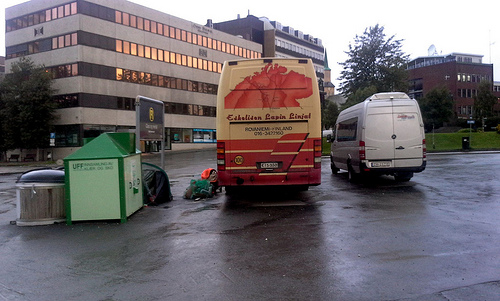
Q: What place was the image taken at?
A: It was taken at the parking lot.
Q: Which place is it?
A: It is a parking lot.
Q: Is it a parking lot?
A: Yes, it is a parking lot.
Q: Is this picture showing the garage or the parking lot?
A: It is showing the parking lot.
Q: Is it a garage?
A: No, it is a parking lot.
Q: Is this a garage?
A: No, it is a parking lot.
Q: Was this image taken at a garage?
A: No, the picture was taken in a parking lot.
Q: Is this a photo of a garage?
A: No, the picture is showing a parking lot.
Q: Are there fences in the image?
A: No, there are no fences.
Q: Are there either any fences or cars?
A: No, there are no fences or cars.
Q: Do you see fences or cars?
A: No, there are no fences or cars.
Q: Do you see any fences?
A: No, there are no fences.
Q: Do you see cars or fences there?
A: No, there are no fences or cars.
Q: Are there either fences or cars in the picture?
A: No, there are no fences or cars.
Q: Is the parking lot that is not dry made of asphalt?
A: Yes, the parking lot is made of asphalt.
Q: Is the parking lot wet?
A: Yes, the parking lot is wet.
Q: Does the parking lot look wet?
A: Yes, the parking lot is wet.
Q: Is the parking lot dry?
A: No, the parking lot is wet.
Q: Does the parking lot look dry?
A: No, the parking lot is wet.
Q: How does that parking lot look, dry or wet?
A: The parking lot is wet.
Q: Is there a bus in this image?
A: Yes, there is a bus.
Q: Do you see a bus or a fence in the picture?
A: Yes, there is a bus.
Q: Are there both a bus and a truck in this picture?
A: No, there is a bus but no trucks.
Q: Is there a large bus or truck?
A: Yes, there is a large bus.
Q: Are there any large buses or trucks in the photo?
A: Yes, there is a large bus.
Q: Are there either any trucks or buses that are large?
A: Yes, the bus is large.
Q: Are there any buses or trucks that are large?
A: Yes, the bus is large.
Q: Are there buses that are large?
A: Yes, there is a large bus.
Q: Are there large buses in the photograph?
A: Yes, there is a large bus.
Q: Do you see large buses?
A: Yes, there is a large bus.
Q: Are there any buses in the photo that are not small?
A: Yes, there is a large bus.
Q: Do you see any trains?
A: No, there are no trains.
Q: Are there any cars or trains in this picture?
A: No, there are no trains or cars.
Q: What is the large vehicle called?
A: The vehicle is a bus.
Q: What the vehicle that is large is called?
A: The vehicle is a bus.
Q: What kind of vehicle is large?
A: The vehicle is a bus.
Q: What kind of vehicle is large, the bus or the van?
A: The bus is large.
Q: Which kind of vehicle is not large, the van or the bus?
A: The van is not large.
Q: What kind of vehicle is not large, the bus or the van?
A: The van is not large.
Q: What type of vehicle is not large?
A: The vehicle is a van.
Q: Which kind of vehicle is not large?
A: The vehicle is a van.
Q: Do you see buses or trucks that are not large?
A: No, there is a bus but it is large.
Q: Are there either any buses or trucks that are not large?
A: No, there is a bus but it is large.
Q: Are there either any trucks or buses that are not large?
A: No, there is a bus but it is large.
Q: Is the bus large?
A: Yes, the bus is large.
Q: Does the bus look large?
A: Yes, the bus is large.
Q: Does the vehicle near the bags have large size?
A: Yes, the bus is large.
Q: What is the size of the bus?
A: The bus is large.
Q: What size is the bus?
A: The bus is large.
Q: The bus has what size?
A: The bus is large.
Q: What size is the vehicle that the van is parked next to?
A: The bus is large.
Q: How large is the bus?
A: The bus is large.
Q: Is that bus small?
A: No, the bus is large.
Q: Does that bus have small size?
A: No, the bus is large.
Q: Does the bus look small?
A: No, the bus is large.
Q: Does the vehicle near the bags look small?
A: No, the bus is large.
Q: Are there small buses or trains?
A: No, there is a bus but it is large.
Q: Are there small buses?
A: No, there is a bus but it is large.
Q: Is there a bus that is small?
A: No, there is a bus but it is large.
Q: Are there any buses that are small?
A: No, there is a bus but it is large.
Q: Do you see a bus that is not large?
A: No, there is a bus but it is large.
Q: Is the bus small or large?
A: The bus is large.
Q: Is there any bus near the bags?
A: Yes, there is a bus near the bags.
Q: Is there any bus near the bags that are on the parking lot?
A: Yes, there is a bus near the bags.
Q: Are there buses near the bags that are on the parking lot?
A: Yes, there is a bus near the bags.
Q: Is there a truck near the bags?
A: No, there is a bus near the bags.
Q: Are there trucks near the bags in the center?
A: No, there is a bus near the bags.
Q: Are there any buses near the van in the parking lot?
A: Yes, there is a bus near the van.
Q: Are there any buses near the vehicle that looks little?
A: Yes, there is a bus near the van.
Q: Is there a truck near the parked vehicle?
A: No, there is a bus near the van.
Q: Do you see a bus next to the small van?
A: Yes, there is a bus next to the van.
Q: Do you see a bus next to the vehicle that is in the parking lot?
A: Yes, there is a bus next to the van.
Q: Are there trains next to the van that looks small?
A: No, there is a bus next to the van.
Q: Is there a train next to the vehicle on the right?
A: No, there is a bus next to the van.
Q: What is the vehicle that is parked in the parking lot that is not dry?
A: The vehicle is a bus.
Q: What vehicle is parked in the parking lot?
A: The vehicle is a bus.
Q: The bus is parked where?
A: The bus is parked in the parking lot.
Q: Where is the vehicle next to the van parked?
A: The bus is parked in the parking lot.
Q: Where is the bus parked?
A: The bus is parked in the parking lot.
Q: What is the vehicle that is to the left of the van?
A: The vehicle is a bus.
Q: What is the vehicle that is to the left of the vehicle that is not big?
A: The vehicle is a bus.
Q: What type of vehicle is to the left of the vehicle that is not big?
A: The vehicle is a bus.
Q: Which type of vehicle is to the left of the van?
A: The vehicle is a bus.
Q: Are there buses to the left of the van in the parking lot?
A: Yes, there is a bus to the left of the van.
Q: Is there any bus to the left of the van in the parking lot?
A: Yes, there is a bus to the left of the van.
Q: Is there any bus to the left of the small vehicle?
A: Yes, there is a bus to the left of the van.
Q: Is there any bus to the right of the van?
A: No, the bus is to the left of the van.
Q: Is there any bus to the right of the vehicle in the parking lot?
A: No, the bus is to the left of the van.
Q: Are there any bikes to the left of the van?
A: No, there is a bus to the left of the van.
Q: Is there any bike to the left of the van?
A: No, there is a bus to the left of the van.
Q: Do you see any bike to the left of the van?
A: No, there is a bus to the left of the van.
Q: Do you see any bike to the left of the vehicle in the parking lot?
A: No, there is a bus to the left of the van.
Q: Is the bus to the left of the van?
A: Yes, the bus is to the left of the van.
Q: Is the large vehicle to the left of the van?
A: Yes, the bus is to the left of the van.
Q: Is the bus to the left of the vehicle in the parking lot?
A: Yes, the bus is to the left of the van.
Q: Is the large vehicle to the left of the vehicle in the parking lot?
A: Yes, the bus is to the left of the van.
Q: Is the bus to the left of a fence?
A: No, the bus is to the left of the van.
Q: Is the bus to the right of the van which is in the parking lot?
A: No, the bus is to the left of the van.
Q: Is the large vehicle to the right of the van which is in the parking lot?
A: No, the bus is to the left of the van.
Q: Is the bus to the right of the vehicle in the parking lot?
A: No, the bus is to the left of the van.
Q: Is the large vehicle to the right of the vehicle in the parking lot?
A: No, the bus is to the left of the van.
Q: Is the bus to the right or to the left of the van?
A: The bus is to the left of the van.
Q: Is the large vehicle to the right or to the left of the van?
A: The bus is to the left of the van.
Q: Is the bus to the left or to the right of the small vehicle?
A: The bus is to the left of the van.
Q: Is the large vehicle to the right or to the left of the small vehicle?
A: The bus is to the left of the van.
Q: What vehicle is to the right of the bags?
A: The vehicle is a bus.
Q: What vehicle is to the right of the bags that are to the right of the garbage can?
A: The vehicle is a bus.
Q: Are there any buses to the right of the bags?
A: Yes, there is a bus to the right of the bags.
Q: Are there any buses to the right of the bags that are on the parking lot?
A: Yes, there is a bus to the right of the bags.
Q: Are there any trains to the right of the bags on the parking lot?
A: No, there is a bus to the right of the bags.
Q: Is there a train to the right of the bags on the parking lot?
A: No, there is a bus to the right of the bags.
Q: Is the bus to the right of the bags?
A: Yes, the bus is to the right of the bags.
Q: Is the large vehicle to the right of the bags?
A: Yes, the bus is to the right of the bags.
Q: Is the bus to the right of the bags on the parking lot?
A: Yes, the bus is to the right of the bags.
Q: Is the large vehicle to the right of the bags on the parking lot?
A: Yes, the bus is to the right of the bags.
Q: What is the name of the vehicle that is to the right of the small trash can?
A: The vehicle is a bus.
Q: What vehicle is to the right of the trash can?
A: The vehicle is a bus.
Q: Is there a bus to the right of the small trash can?
A: Yes, there is a bus to the right of the trashcan.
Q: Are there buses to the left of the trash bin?
A: No, the bus is to the right of the trash bin.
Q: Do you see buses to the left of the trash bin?
A: No, the bus is to the right of the trash bin.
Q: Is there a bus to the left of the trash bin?
A: No, the bus is to the right of the trash bin.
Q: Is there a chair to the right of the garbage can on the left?
A: No, there is a bus to the right of the trashcan.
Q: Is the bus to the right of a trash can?
A: Yes, the bus is to the right of a trash can.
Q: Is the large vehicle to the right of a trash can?
A: Yes, the bus is to the right of a trash can.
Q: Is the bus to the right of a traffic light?
A: No, the bus is to the right of a trash can.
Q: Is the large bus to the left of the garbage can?
A: No, the bus is to the right of the garbage can.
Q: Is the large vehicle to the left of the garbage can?
A: No, the bus is to the right of the garbage can.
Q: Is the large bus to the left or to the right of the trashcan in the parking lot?
A: The bus is to the right of the trashcan.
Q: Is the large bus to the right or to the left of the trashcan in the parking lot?
A: The bus is to the right of the trashcan.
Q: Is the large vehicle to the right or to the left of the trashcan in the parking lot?
A: The bus is to the right of the trashcan.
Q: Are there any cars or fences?
A: No, there are no cars or fences.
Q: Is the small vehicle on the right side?
A: Yes, the van is on the right of the image.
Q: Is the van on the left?
A: No, the van is on the right of the image.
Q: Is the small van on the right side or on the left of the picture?
A: The van is on the right of the image.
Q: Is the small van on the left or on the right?
A: The van is on the right of the image.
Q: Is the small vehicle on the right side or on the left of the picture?
A: The van is on the right of the image.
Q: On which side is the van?
A: The van is on the right of the image.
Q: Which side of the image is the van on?
A: The van is on the right of the image.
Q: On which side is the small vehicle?
A: The van is on the right of the image.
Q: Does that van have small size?
A: Yes, the van is small.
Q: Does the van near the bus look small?
A: Yes, the van is small.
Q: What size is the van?
A: The van is small.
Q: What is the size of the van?
A: The van is small.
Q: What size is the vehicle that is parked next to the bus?
A: The van is small.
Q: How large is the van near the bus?
A: The van is small.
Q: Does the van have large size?
A: No, the van is small.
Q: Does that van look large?
A: No, the van is small.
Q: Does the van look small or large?
A: The van is small.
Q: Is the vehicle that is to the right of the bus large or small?
A: The van is small.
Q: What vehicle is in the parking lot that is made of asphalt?
A: The vehicle is a van.